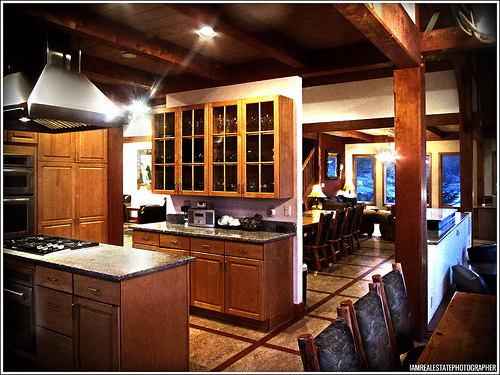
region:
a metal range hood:
[5, 43, 129, 133]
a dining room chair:
[297, 305, 362, 370]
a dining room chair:
[339, 281, 396, 373]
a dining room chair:
[373, 263, 429, 365]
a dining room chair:
[304, 212, 331, 272]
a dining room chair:
[331, 208, 343, 261]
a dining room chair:
[341, 206, 356, 258]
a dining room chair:
[353, 202, 364, 253]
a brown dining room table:
[413, 289, 494, 370]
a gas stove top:
[2, 234, 99, 254]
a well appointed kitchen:
[12, 7, 489, 365]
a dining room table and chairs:
[308, 198, 367, 266]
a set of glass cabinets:
[157, 106, 299, 197]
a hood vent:
[14, 37, 92, 139]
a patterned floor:
[208, 328, 275, 369]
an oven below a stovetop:
[10, 270, 38, 347]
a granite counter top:
[75, 245, 142, 272]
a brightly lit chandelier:
[372, 140, 400, 177]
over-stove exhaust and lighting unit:
[3, 44, 134, 136]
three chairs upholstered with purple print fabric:
[296, 261, 431, 374]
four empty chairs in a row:
[303, 200, 367, 272]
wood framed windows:
[350, 149, 465, 211]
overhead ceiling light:
[196, 22, 216, 43]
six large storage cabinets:
[34, 93, 110, 245]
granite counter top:
[128, 210, 300, 246]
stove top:
[3, 232, 100, 258]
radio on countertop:
[185, 205, 217, 228]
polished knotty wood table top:
[411, 287, 498, 374]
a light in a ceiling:
[197, 26, 215, 42]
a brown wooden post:
[393, 68, 429, 342]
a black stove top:
[0, 233, 99, 256]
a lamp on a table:
[305, 183, 327, 207]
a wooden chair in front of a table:
[372, 261, 427, 366]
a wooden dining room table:
[410, 291, 496, 371]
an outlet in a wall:
[282, 203, 291, 218]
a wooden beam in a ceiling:
[14, 5, 231, 84]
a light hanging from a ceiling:
[372, 148, 401, 165]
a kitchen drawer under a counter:
[225, 239, 265, 261]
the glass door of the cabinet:
[151, 108, 181, 195]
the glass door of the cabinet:
[179, 103, 206, 191]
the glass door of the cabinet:
[210, 101, 242, 195]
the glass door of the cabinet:
[244, 93, 278, 198]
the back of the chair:
[296, 308, 357, 372]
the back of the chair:
[343, 283, 395, 368]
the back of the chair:
[372, 260, 421, 347]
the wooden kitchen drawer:
[34, 266, 72, 293]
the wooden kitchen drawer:
[72, 272, 121, 305]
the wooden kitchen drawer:
[223, 241, 264, 259]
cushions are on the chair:
[324, 290, 417, 358]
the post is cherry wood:
[388, 79, 429, 346]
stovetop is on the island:
[30, 234, 86, 251]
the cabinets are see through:
[158, 113, 269, 189]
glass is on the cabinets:
[157, 107, 286, 194]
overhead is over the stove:
[16, 57, 124, 146]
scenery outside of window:
[352, 152, 378, 204]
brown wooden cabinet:
[144, 101, 294, 205]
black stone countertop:
[50, 230, 187, 280]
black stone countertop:
[135, 215, 286, 245]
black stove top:
[8, 221, 90, 256]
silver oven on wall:
[1, 148, 46, 245]